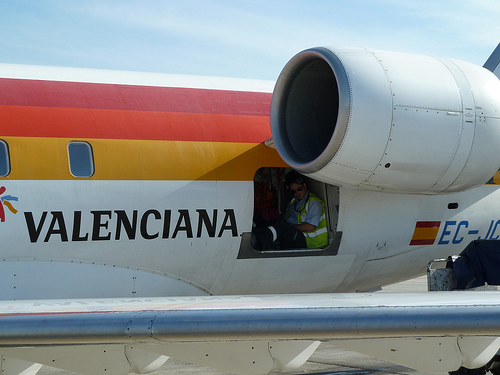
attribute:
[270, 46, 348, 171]
ring — silver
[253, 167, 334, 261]
hole — small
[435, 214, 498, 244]
ec-jg — blue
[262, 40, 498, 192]
engine — silver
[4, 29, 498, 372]
plane — large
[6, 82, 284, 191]
stripe — red, maroon, orange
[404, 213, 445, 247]
box — orange, red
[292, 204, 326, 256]
vest — green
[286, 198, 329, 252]
vest — green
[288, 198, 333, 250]
vest — reflective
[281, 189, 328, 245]
vest — reflective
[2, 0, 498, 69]
sky — blue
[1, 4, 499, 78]
clouds — white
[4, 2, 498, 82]
sky — blue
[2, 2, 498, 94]
sky — blue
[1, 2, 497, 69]
clouds — white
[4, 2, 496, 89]
clouds — white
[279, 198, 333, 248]
vest — green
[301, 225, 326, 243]
stripe — white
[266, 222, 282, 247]
stripe — white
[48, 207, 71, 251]
letter — a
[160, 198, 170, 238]
letter — I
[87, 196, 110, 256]
letter — e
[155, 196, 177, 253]
letter — n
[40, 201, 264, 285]
letter — black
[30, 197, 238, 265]
letter — black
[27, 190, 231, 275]
letter — black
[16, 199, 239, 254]
letter — black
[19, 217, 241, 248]
letter — black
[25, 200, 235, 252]
letter — black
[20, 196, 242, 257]
letter — black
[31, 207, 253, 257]
letter — black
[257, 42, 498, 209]
engine — large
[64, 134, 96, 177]
window — small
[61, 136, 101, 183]
window — small, glass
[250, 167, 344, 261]
door — open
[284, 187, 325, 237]
person — sitting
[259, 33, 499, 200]
engine — large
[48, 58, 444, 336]
plane — red orange and yellow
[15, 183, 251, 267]
letters — black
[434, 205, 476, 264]
letters — blue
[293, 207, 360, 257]
bag — green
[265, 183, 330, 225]
shirt — blue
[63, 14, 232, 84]
sky — blue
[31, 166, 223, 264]
sign — red and orange